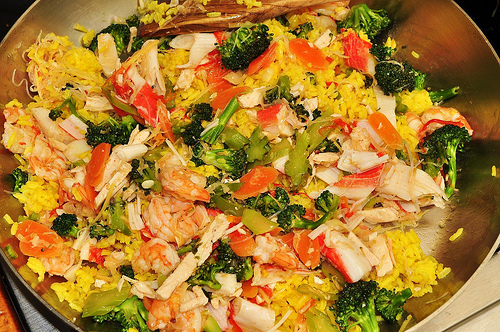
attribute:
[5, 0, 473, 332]
meal — colorful, tasty, yummy, seafood, vegetable, delicious, fatastic, fantastic, delightful, nice, great, special, flavorful, attractive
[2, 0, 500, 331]
bowl — silver, large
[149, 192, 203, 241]
shrimp — pink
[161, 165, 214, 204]
shrimp — orange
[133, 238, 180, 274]
shrimp — orange, pink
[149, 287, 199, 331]
shrimp — orange, pink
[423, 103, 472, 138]
shrimp — orange, pink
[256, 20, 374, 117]
rice — yellow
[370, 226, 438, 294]
rice — yellow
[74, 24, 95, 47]
rice — yellow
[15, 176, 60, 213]
rice — yellow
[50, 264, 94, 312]
rice — yellow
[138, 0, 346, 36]
spoon — wood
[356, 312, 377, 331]
stem — green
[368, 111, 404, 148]
carrot — cooked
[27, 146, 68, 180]
shrimp — orange, pink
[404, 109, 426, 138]
shrimp — orange, pink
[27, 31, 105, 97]
rice — yellow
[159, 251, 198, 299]
chunk — chicken